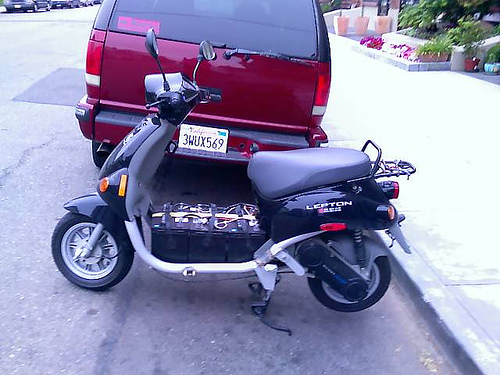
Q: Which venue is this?
A: This is a sidewalk.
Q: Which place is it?
A: It is a sidewalk.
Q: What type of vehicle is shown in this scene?
A: The vehicle is a car.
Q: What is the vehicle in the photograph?
A: The vehicle is a car.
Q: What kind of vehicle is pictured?
A: The vehicle is a car.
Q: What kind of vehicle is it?
A: The vehicle is a car.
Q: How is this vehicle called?
A: This is a car.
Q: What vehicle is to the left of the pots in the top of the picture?
A: The vehicle is a car.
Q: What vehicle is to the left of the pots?
A: The vehicle is a car.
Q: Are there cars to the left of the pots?
A: Yes, there is a car to the left of the pots.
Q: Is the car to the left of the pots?
A: Yes, the car is to the left of the pots.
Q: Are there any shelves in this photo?
A: No, there are no shelves.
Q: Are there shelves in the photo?
A: No, there are no shelves.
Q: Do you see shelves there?
A: No, there are no shelves.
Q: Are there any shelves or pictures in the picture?
A: No, there are no shelves or pictures.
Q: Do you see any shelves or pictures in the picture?
A: No, there are no shelves or pictures.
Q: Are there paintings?
A: No, there are no paintings.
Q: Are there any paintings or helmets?
A: No, there are no paintings or helmets.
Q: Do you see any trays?
A: No, there are no trays.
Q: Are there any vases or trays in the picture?
A: No, there are no trays or vases.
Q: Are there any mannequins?
A: No, there are no mannequins.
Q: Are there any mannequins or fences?
A: No, there are no mannequins or fences.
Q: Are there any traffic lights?
A: No, there are no traffic lights.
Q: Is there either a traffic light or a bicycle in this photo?
A: No, there are no traffic lights or bicycles.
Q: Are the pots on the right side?
A: Yes, the pots are on the right of the image.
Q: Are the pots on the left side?
A: No, the pots are on the right of the image.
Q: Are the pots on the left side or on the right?
A: The pots are on the right of the image.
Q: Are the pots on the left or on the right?
A: The pots are on the right of the image.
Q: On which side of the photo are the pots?
A: The pots are on the right of the image.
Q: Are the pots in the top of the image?
A: Yes, the pots are in the top of the image.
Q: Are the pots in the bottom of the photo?
A: No, the pots are in the top of the image.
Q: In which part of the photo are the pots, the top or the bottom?
A: The pots are in the top of the image.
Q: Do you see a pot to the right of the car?
A: Yes, there are pots to the right of the car.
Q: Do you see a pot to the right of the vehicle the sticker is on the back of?
A: Yes, there are pots to the right of the car.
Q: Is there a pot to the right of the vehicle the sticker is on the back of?
A: Yes, there are pots to the right of the car.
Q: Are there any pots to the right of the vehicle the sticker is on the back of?
A: Yes, there are pots to the right of the car.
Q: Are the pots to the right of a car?
A: Yes, the pots are to the right of a car.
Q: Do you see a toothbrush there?
A: No, there are no toothbrushes.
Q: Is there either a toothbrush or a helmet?
A: No, there are no toothbrushes or helmets.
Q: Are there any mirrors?
A: Yes, there is a mirror.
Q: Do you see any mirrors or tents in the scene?
A: Yes, there is a mirror.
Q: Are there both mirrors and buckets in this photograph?
A: No, there is a mirror but no buckets.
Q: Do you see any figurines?
A: No, there are no figurines.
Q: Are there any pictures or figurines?
A: No, there are no figurines or pictures.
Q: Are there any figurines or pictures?
A: No, there are no figurines or pictures.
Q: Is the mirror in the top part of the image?
A: Yes, the mirror is in the top of the image.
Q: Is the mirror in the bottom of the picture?
A: No, the mirror is in the top of the image.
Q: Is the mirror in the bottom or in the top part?
A: The mirror is in the top of the image.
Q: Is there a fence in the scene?
A: No, there are no fences.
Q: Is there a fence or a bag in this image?
A: No, there are no fences or bags.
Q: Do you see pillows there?
A: No, there are no pillows.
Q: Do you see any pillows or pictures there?
A: No, there are no pillows or pictures.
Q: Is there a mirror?
A: Yes, there is a mirror.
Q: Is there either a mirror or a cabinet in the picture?
A: Yes, there is a mirror.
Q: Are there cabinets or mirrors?
A: Yes, there is a mirror.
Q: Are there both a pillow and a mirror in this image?
A: No, there is a mirror but no pillows.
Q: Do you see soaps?
A: No, there are no soaps.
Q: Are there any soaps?
A: No, there are no soaps.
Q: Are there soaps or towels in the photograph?
A: No, there are no soaps or towels.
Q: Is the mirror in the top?
A: Yes, the mirror is in the top of the image.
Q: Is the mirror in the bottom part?
A: No, the mirror is in the top of the image.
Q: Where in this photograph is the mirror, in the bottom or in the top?
A: The mirror is in the top of the image.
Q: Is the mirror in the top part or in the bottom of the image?
A: The mirror is in the top of the image.